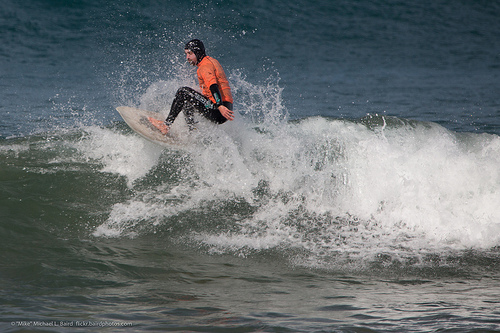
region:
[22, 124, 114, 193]
white and blue waves in ocean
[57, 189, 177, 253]
white and blue waves in ocean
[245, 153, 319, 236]
white and blue waves in ocean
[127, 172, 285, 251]
white and blue waves in ocean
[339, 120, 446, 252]
white and blue waves in ocean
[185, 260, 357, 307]
white and blue waves in ocean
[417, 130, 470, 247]
white and blue waves in ocean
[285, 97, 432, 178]
white and blue waves in ocean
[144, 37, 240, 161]
young man surfing in ocean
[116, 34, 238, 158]
man surfing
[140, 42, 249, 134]
man suring in wet ocean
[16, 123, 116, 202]
white and gray waves in ocean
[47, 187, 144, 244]
white and gray waves in ocean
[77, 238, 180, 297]
white and gray waves in ocean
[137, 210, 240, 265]
white and gray waves in ocean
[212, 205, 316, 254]
white and gray waves in ocean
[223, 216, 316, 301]
white and gray waves in ocean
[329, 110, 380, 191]
white and gray waves in ocean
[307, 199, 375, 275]
white and gray waves in ocean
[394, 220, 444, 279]
white and gray waves in ocean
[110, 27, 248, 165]
Man surfboarding on water.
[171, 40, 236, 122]
Orange shirt on man.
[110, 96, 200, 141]
White surfboard on waves.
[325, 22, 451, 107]
Gray blue water in the background.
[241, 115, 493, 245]
White splashed water on the surface.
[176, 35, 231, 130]
Man wearing a black hat on wet suit.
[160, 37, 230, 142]
Man is wearing black wet suit pants.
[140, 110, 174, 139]
Barefoot on top of surfboard.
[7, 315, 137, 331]
Photograph is copyrighted.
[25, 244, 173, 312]
Gray colored water in front of wave.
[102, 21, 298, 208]
the man is surfing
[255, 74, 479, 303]
the wave is rolling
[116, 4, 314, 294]
the water is splashing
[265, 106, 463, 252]
the wave is white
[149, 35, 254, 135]
the man is wearing a wet suit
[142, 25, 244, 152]
the wet suit is black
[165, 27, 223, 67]
the man is wearing a tight hood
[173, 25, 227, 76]
the tight hood is black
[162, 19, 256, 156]
man is wearing an orange shirt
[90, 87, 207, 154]
the surfboard is white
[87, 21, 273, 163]
a person surfing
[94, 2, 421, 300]
a man surfing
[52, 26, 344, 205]
a person surfing in water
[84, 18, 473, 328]
a man surfing the water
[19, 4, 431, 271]
a person surfing a wave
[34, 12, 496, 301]
a man surfing a wave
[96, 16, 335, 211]
a man wearing an orange shirt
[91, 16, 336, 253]
a man on a surfboard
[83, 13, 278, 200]
a man riding a surfboard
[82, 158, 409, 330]
a body of water